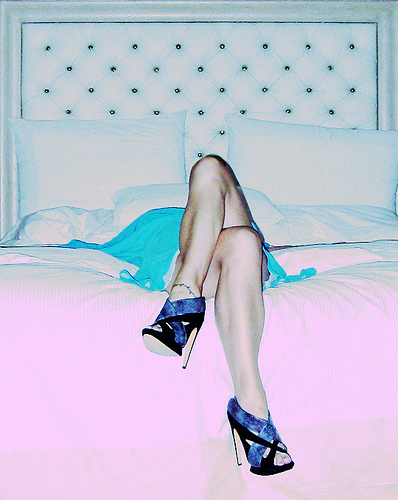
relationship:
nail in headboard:
[47, 47, 50, 50] [0, 0, 397, 244]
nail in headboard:
[88, 44, 93, 52] [0, 0, 397, 244]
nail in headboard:
[130, 43, 141, 54] [0, 0, 397, 244]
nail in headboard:
[175, 42, 182, 50] [0, 0, 397, 244]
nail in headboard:
[218, 43, 226, 51] [0, 0, 397, 244]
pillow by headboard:
[10, 115, 190, 231] [0, 0, 397, 244]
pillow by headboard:
[227, 114, 397, 221] [0, 0, 397, 244]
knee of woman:
[190, 155, 237, 194] [110, 155, 296, 476]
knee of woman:
[227, 226, 263, 270] [110, 155, 296, 476]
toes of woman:
[272, 447, 293, 466] [110, 155, 296, 476]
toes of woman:
[144, 319, 162, 332] [110, 155, 296, 476]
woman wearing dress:
[110, 155, 296, 476] [61, 206, 318, 289]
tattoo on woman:
[168, 283, 196, 299] [110, 155, 296, 476]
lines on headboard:
[21, 23, 377, 184] [0, 0, 397, 244]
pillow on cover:
[10, 115, 190, 231] [0, 209, 395, 500]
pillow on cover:
[227, 114, 397, 221] [0, 209, 395, 500]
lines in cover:
[2, 203, 397, 312] [0, 209, 395, 500]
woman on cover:
[110, 155, 296, 476] [0, 209, 395, 500]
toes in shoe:
[272, 447, 293, 466] [227, 395, 295, 476]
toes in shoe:
[144, 319, 162, 332] [140, 293, 206, 370]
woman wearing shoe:
[110, 155, 296, 476] [140, 293, 206, 370]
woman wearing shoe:
[110, 155, 296, 476] [227, 395, 295, 476]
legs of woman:
[142, 158, 293, 475] [110, 155, 296, 476]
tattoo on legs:
[168, 283, 196, 299] [142, 158, 293, 475]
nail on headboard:
[47, 47, 50, 50] [0, 0, 397, 244]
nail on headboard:
[88, 44, 93, 52] [0, 0, 397, 244]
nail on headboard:
[130, 43, 141, 54] [0, 0, 397, 244]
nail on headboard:
[175, 42, 182, 50] [0, 0, 397, 244]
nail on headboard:
[218, 43, 226, 51] [0, 0, 397, 244]